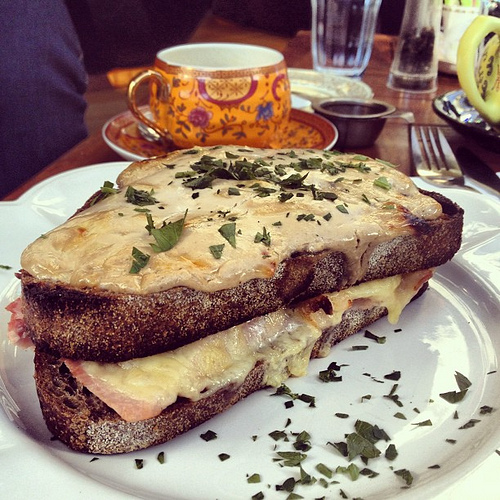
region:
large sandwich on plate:
[19, 144, 463, 452]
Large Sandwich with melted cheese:
[21, 145, 466, 452]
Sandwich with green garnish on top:
[19, 143, 463, 453]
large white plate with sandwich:
[0, 186, 495, 498]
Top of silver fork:
[409, 126, 486, 191]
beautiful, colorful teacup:
[124, 43, 288, 148]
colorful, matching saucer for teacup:
[102, 105, 339, 158]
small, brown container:
[312, 98, 395, 146]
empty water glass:
[312, 1, 382, 75]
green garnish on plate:
[132, 325, 484, 497]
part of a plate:
[248, 435, 288, 477]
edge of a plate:
[161, 406, 203, 449]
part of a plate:
[194, 465, 221, 490]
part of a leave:
[348, 434, 371, 447]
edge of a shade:
[425, 343, 447, 367]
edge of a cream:
[168, 391, 193, 408]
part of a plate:
[177, 458, 202, 490]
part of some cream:
[161, 383, 196, 411]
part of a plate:
[176, 450, 203, 476]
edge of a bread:
[244, 270, 267, 295]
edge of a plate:
[433, 405, 455, 435]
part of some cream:
[175, 359, 200, 382]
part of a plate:
[166, 463, 196, 498]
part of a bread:
[178, 387, 203, 409]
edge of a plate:
[454, 432, 477, 467]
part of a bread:
[198, 379, 243, 434]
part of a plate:
[201, 460, 236, 490]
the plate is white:
[315, 423, 364, 488]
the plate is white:
[386, 387, 456, 496]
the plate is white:
[383, 422, 413, 494]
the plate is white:
[336, 408, 381, 485]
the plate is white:
[360, 405, 426, 490]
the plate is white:
[275, 367, 377, 485]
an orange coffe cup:
[134, 35, 287, 146]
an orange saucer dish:
[96, 96, 333, 164]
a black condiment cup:
[312, 90, 394, 145]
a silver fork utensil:
[404, 118, 479, 196]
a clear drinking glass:
[306, 0, 377, 78]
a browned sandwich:
[13, 133, 458, 438]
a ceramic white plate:
[6, 155, 496, 498]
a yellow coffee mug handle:
[454, 12, 498, 129]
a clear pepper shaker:
[385, 0, 443, 92]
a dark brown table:
[14, 2, 495, 202]